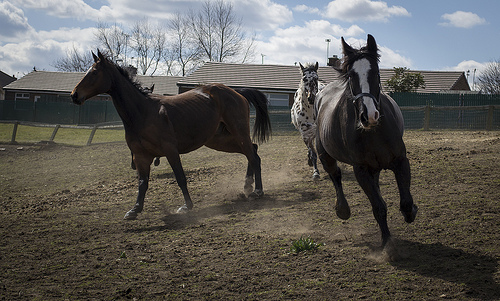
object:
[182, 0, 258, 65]
trees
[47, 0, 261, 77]
no leaves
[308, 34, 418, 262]
horse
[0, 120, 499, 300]
field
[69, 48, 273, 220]
horse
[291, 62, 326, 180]
horse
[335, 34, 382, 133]
head